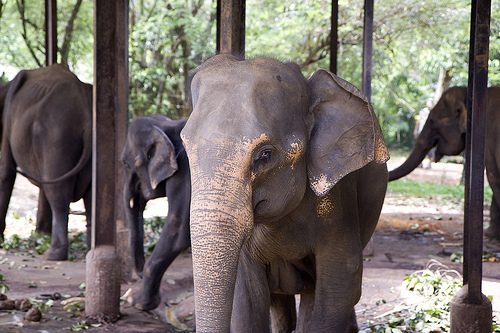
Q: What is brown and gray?
A: Trunk of elephant.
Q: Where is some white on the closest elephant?
A: Ear.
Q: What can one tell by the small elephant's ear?
A: Indian elephant.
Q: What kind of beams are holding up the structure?
A: Steel.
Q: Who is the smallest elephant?
A: Second from left.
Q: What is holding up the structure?
A: It's poles.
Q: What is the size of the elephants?
A: Their huge.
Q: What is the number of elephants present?
A: It's four.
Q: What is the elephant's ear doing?
A: It's flapping.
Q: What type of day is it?
A: It's daytime.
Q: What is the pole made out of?
A: It's wood.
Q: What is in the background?
A: It's bushes.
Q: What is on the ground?
A: It's dirt.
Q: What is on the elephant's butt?
A: It's a tail.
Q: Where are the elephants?
A: On the ground.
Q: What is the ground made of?
A: Dirt.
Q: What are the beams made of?
A: Metal.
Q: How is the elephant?
A: Standing.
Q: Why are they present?
A: Habitat.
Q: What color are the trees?
A: Green.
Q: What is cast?
A: Shadows.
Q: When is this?
A: Daytime.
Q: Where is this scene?
A: Wildlife refuge.